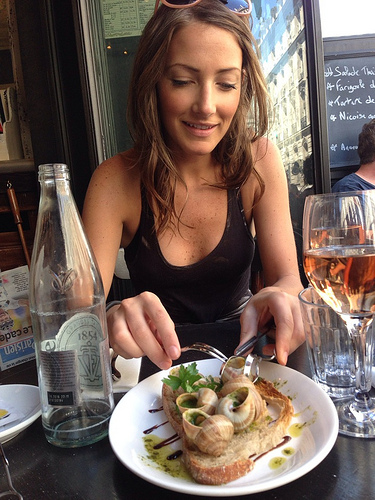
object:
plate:
[0, 384, 45, 444]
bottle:
[27, 161, 115, 451]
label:
[40, 349, 77, 410]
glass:
[296, 284, 374, 400]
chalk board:
[322, 55, 375, 168]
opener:
[221, 346, 259, 385]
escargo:
[181, 408, 233, 457]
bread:
[161, 367, 298, 488]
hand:
[234, 280, 310, 366]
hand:
[107, 290, 181, 371]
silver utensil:
[218, 319, 274, 382]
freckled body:
[155, 185, 229, 264]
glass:
[300, 185, 373, 439]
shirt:
[123, 151, 256, 354]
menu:
[323, 63, 375, 122]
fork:
[181, 343, 228, 365]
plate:
[106, 359, 338, 500]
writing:
[339, 111, 346, 121]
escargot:
[215, 386, 257, 434]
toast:
[161, 357, 294, 485]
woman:
[64, 0, 310, 379]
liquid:
[302, 244, 375, 317]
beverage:
[302, 246, 374, 316]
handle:
[234, 316, 275, 358]